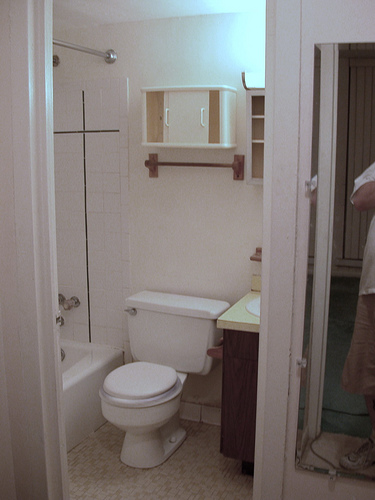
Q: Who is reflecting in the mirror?
A: A person.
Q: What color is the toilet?
A: White.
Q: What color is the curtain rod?
A: Silver.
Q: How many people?
A: One.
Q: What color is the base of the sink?
A: Brown.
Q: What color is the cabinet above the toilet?
A: Cream.